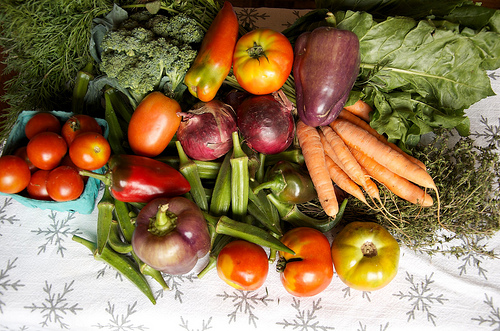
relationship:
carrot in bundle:
[296, 118, 338, 218] [297, 95, 438, 215]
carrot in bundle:
[322, 125, 367, 183] [297, 95, 438, 215]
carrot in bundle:
[334, 121, 434, 187] [297, 95, 438, 215]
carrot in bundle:
[351, 149, 437, 208] [297, 95, 438, 215]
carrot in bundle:
[350, 97, 375, 120] [297, 95, 438, 215]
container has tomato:
[1, 103, 116, 208] [50, 162, 84, 202]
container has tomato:
[1, 103, 116, 208] [71, 133, 113, 166]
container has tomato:
[1, 103, 116, 208] [25, 110, 63, 139]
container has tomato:
[1, 103, 116, 208] [0, 154, 31, 195]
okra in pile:
[230, 129, 254, 217] [89, 91, 295, 300]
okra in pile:
[172, 141, 209, 208] [89, 91, 295, 300]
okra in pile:
[218, 213, 297, 257] [89, 91, 295, 300]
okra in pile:
[70, 237, 157, 305] [89, 91, 295, 300]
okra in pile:
[93, 177, 116, 253] [89, 91, 295, 300]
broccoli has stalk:
[93, 7, 199, 96] [104, 58, 159, 96]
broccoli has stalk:
[93, 7, 199, 96] [98, 27, 150, 59]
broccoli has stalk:
[93, 7, 199, 96] [151, 39, 194, 90]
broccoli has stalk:
[93, 7, 199, 96] [145, 10, 200, 46]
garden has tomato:
[0, 2, 498, 306] [233, 29, 295, 97]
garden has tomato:
[0, 2, 498, 306] [131, 91, 180, 155]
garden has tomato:
[0, 2, 498, 306] [71, 133, 113, 166]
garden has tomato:
[0, 2, 498, 306] [25, 110, 63, 139]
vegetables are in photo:
[6, 5, 499, 295] [0, 0, 499, 331]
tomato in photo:
[131, 91, 180, 155] [0, 0, 499, 331]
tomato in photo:
[233, 29, 295, 97] [0, 0, 499, 331]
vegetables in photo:
[329, 218, 398, 289] [0, 0, 499, 331]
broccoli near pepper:
[93, 7, 199, 96] [293, 20, 359, 128]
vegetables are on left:
[6, 5, 499, 295] [1, 3, 218, 137]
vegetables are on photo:
[6, 5, 499, 295] [0, 0, 499, 331]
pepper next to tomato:
[189, 5, 240, 106] [233, 29, 295, 97]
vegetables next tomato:
[329, 218, 398, 289] [277, 226, 334, 297]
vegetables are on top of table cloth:
[6, 5, 499, 295] [0, 155, 494, 329]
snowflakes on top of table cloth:
[20, 272, 87, 330] [0, 155, 494, 329]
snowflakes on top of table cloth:
[93, 294, 147, 329] [0, 155, 494, 329]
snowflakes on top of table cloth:
[274, 296, 339, 330] [0, 155, 494, 329]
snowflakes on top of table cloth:
[272, 299, 332, 330] [0, 155, 494, 329]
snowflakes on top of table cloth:
[388, 270, 451, 328] [0, 155, 494, 329]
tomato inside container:
[71, 133, 113, 166] [1, 103, 116, 208]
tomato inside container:
[25, 110, 63, 139] [1, 103, 116, 208]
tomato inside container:
[0, 154, 31, 195] [1, 103, 116, 208]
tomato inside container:
[50, 162, 84, 202] [1, 103, 116, 208]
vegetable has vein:
[308, 13, 497, 134] [361, 62, 489, 91]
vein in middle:
[361, 62, 489, 91] [355, 39, 499, 105]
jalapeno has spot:
[189, 5, 240, 106] [192, 63, 216, 83]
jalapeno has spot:
[189, 5, 240, 106] [189, 55, 228, 96]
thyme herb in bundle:
[351, 136, 498, 250] [297, 95, 438, 215]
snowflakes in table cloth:
[20, 272, 87, 330] [0, 155, 494, 329]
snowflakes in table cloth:
[93, 294, 147, 329] [0, 155, 494, 329]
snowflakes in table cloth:
[274, 296, 339, 330] [0, 155, 494, 329]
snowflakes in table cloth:
[272, 299, 332, 330] [0, 155, 494, 329]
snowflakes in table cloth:
[388, 270, 451, 328] [0, 155, 494, 329]